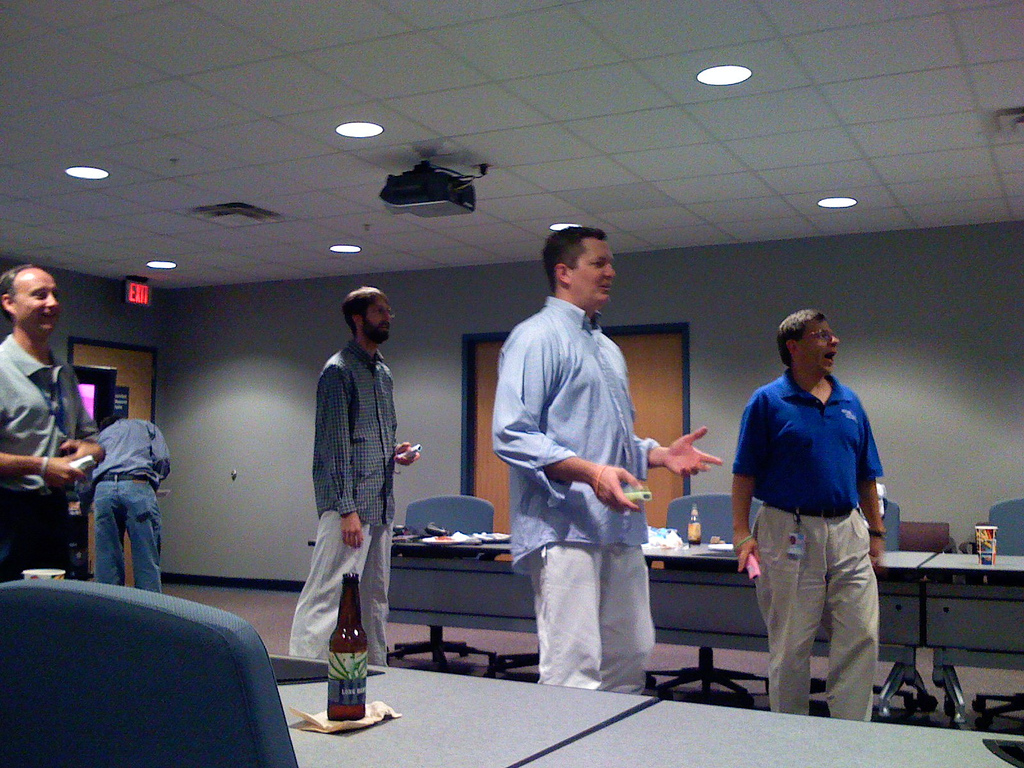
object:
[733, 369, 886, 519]
shirt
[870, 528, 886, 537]
watch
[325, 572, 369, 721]
bottle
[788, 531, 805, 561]
tag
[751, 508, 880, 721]
pants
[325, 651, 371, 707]
label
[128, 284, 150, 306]
exit sign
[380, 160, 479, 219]
projector device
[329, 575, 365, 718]
bottle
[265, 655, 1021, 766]
table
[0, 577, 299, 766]
chair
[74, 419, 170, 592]
man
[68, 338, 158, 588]
door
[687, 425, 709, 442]
finger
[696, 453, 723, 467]
finger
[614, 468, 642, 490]
finger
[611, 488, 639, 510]
finger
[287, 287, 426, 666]
person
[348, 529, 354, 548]
finger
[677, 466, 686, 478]
finger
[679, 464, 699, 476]
finger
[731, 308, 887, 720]
person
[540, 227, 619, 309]
head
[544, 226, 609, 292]
hair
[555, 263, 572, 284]
ear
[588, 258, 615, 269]
eye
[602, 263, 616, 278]
nose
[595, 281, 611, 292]
mouth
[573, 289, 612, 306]
chin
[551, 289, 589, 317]
neck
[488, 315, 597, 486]
arm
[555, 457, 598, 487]
wrist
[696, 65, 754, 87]
light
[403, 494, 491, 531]
chair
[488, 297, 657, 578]
shirt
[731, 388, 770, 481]
sleeve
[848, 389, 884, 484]
sleeve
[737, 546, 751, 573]
finger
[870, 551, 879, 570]
finger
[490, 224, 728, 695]
man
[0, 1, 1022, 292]
ceiling